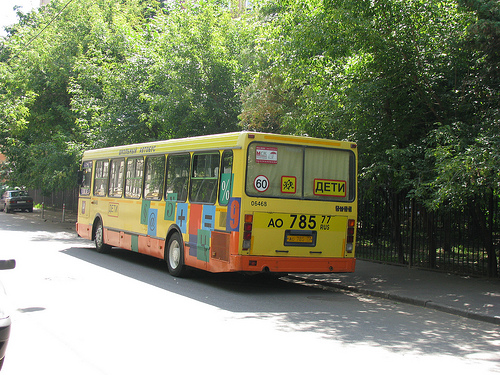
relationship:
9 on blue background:
[227, 200, 238, 233] [225, 194, 243, 228]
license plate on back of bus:
[287, 235, 313, 243] [69, 123, 368, 290]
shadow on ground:
[64, 225, 394, 364] [1, 218, 499, 370]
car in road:
[3, 187, 46, 208] [0, 212, 499, 375]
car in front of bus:
[3, 187, 46, 208] [78, 140, 386, 266]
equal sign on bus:
[202, 210, 214, 229] [69, 123, 368, 290]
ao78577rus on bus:
[268, 211, 331, 227] [60, 123, 421, 288]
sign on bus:
[313, 177, 346, 197] [69, 123, 368, 290]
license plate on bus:
[281, 230, 316, 250] [69, 123, 368, 290]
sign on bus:
[254, 170, 270, 193] [39, 117, 384, 245]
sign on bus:
[313, 176, 350, 199] [69, 123, 368, 290]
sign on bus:
[251, 147, 313, 171] [51, 116, 322, 274]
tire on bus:
[94, 220, 112, 255] [69, 123, 368, 290]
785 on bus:
[289, 209, 316, 231] [69, 123, 368, 290]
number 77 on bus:
[318, 212, 333, 225] [69, 123, 368, 290]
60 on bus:
[248, 173, 280, 195] [66, 127, 363, 274]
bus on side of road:
[74, 128, 356, 285] [1, 210, 498, 373]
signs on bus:
[137, 190, 249, 268] [69, 123, 368, 290]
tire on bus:
[161, 227, 186, 278] [69, 123, 368, 290]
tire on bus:
[90, 212, 111, 254] [69, 123, 368, 290]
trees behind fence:
[3, 1, 495, 131] [363, 185, 497, 275]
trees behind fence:
[3, 1, 495, 131] [15, 174, 75, 208]